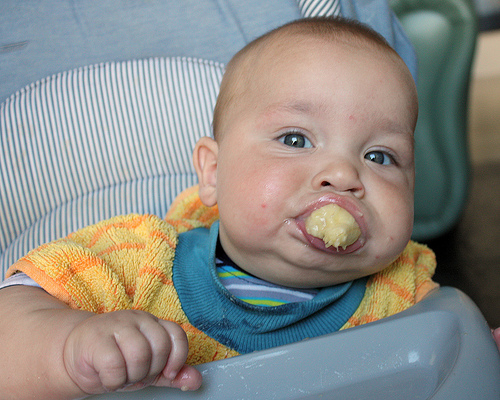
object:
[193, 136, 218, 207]
ear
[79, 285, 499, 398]
object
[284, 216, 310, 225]
water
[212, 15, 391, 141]
hair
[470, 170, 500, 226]
ground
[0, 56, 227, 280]
cushion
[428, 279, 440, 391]
tray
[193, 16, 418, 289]
head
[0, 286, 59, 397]
arm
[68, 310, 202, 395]
clenched fist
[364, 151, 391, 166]
left eye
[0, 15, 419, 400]
baby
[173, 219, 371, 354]
collar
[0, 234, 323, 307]
shirt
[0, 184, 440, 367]
clothing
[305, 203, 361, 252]
food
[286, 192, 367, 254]
baby's mouth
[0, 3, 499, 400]
chair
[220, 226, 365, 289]
neck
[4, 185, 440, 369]
bib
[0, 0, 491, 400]
high chair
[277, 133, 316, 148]
eyes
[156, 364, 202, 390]
thumb